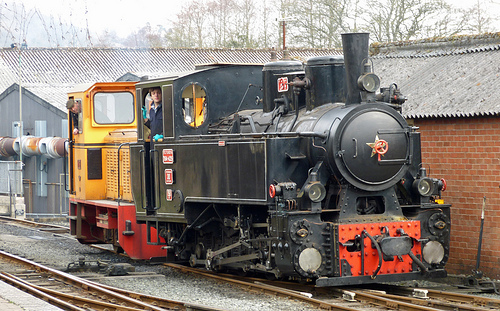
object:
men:
[65, 98, 80, 135]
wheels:
[189, 249, 224, 273]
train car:
[63, 65, 262, 259]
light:
[299, 247, 322, 272]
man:
[141, 86, 164, 162]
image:
[366, 134, 389, 161]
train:
[64, 33, 453, 287]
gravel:
[0, 215, 499, 311]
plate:
[339, 220, 422, 277]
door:
[142, 86, 163, 216]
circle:
[332, 103, 412, 191]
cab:
[64, 81, 140, 203]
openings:
[181, 82, 208, 128]